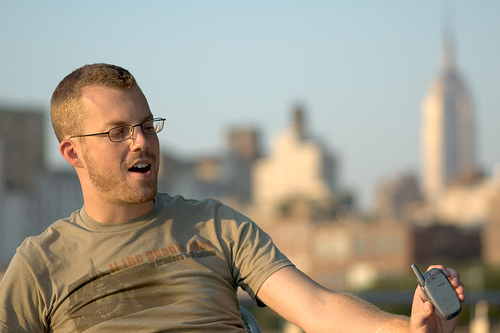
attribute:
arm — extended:
[223, 207, 463, 329]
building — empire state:
[419, 0, 483, 197]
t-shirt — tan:
[0, 194, 302, 326]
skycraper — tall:
[401, 56, 476, 193]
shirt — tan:
[87, 231, 219, 301]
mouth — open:
[115, 154, 149, 178]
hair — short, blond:
[47, 59, 139, 141]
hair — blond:
[90, 174, 120, 194]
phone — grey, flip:
[401, 251, 462, 321]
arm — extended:
[209, 182, 471, 329]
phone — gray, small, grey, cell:
[409, 262, 462, 319]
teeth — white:
[138, 161, 148, 169]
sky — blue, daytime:
[123, 0, 495, 71]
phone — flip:
[395, 253, 495, 324]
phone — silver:
[408, 257, 465, 324]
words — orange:
[105, 238, 212, 272]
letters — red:
[105, 237, 213, 273]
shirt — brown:
[0, 194, 294, 332]